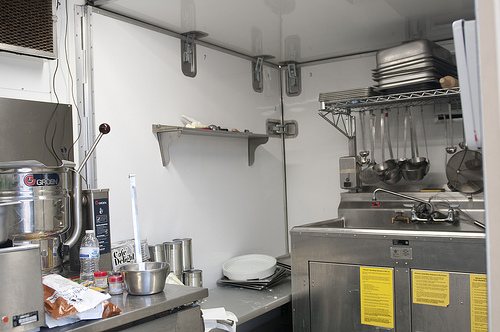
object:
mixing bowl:
[120, 261, 170, 297]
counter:
[43, 280, 208, 331]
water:
[79, 271, 96, 281]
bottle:
[77, 229, 101, 280]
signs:
[358, 266, 395, 329]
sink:
[286, 215, 487, 238]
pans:
[372, 38, 456, 72]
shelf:
[315, 86, 463, 138]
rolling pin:
[438, 75, 456, 88]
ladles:
[398, 104, 429, 182]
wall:
[86, 3, 284, 287]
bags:
[42, 271, 121, 322]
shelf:
[150, 124, 270, 167]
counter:
[101, 258, 291, 331]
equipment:
[289, 191, 490, 332]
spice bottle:
[108, 272, 125, 295]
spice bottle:
[93, 270, 106, 290]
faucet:
[370, 187, 435, 222]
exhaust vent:
[0, 0, 52, 61]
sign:
[411, 268, 450, 308]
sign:
[468, 273, 490, 332]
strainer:
[444, 146, 483, 193]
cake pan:
[223, 252, 276, 280]